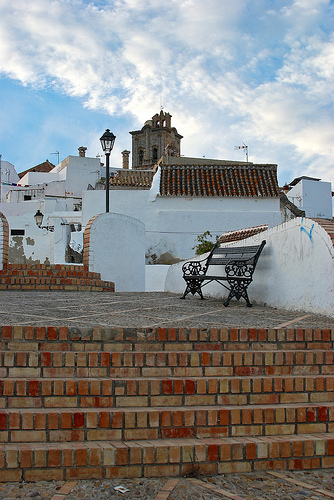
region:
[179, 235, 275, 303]
a black bench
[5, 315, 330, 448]
the first set of brick steps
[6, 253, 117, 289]
a second set of brick steps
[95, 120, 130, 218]
a black light post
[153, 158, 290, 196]
a tiled roof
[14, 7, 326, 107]
a blue and cloudy sky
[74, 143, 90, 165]
a chimney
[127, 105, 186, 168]
a nice looking building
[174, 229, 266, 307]
a black bench with a nice design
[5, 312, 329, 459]
the first brick steps with 5 steps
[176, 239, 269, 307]
black metal bench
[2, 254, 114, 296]
red brick staircase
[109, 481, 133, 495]
trash lying at the bottom of the stairs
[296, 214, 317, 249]
blue graffiti on a white wall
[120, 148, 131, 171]
brick chimney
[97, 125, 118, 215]
black lamp post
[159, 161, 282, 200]
roof made out of terracotta tiles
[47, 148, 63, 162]
metal antenna on a roof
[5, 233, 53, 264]
white paint peeling off of the wall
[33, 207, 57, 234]
protruding wall lamp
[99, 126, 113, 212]
black and glass tall light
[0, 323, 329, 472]
red and dark red bricked stairs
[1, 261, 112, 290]
red and dark red bricked stairs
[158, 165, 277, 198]
multi colored shingled roof top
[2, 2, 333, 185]
bright blue sky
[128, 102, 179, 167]
tall top part of stone building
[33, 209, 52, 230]
light attached to wall of building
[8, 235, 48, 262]
chipped paint on white wall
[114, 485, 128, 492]
piece of paper on ground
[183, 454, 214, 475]
brown tuft of grass under brick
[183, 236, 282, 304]
black bench with scroll design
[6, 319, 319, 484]
red and brown brick steps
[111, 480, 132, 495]
piece of white trash on ground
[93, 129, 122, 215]
lamp on black post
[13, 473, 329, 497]
cobblestone ground at bottom of steps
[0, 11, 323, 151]
bright blue sky with white clouds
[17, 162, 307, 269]
group of white buildings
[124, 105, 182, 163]
tall stone building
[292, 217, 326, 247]
blue paint on wall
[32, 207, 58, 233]
black lamp coming out of wall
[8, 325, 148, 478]
multicolored brick staircase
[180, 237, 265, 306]
ornate black park bench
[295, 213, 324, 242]
blue spray paint on white wall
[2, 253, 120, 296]
short curved brick staircase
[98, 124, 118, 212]
black gas street lamp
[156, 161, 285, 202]
red and yellow clay roofing tiles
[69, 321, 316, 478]
red and yellow brick staircase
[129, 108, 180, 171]
tall old church tower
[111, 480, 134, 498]
trash laying on cobblestone walk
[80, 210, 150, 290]
white wall with red capstones